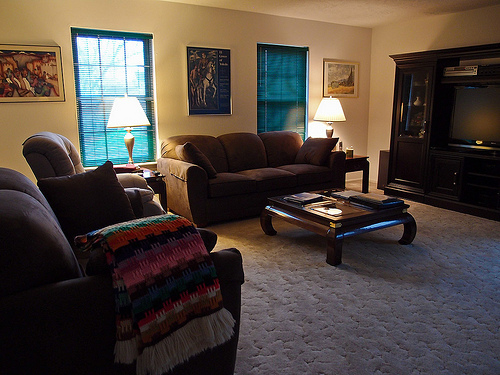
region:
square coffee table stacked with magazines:
[258, 184, 419, 269]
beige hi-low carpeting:
[195, 187, 497, 374]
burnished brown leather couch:
[156, 128, 349, 228]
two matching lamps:
[105, 92, 347, 164]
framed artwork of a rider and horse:
[183, 44, 235, 119]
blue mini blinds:
[67, 25, 160, 168]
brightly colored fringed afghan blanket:
[73, 210, 238, 374]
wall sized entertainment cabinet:
[382, 38, 499, 223]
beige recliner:
[21, 128, 168, 213]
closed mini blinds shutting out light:
[254, 39, 311, 143]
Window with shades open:
[69, 26, 158, 166]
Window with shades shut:
[255, 41, 308, 140]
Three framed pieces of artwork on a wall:
[3, 41, 361, 116]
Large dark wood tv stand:
[381, 38, 498, 223]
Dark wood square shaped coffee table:
[254, 187, 419, 269]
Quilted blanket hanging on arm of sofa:
[76, 213, 238, 370]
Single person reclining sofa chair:
[23, 131, 165, 221]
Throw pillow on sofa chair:
[33, 157, 138, 231]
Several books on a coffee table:
[282, 186, 402, 211]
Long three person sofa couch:
[157, 128, 350, 227]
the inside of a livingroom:
[11, 8, 478, 347]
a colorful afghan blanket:
[78, 212, 245, 373]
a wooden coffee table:
[259, 173, 421, 275]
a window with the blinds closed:
[258, 47, 310, 134]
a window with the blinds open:
[76, 36, 155, 162]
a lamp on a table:
[101, 88, 149, 173]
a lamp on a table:
[311, 93, 351, 147]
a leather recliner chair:
[15, 128, 165, 216]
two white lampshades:
[87, 101, 377, 143]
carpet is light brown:
[318, 257, 406, 367]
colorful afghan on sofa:
[62, 195, 262, 345]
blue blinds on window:
[74, 80, 151, 170]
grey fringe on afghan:
[127, 294, 237, 368]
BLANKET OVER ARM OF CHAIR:
[69, 211, 244, 370]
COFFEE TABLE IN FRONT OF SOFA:
[249, 181, 428, 270]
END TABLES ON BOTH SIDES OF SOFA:
[99, 143, 374, 197]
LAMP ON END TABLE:
[99, 89, 169, 177]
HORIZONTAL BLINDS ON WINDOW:
[62, 29, 163, 163]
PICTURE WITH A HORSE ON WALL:
[178, 34, 246, 128]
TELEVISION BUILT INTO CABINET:
[445, 73, 496, 160]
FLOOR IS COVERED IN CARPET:
[243, 195, 489, 366]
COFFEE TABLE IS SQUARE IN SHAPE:
[247, 182, 424, 243]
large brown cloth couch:
[159, 132, 343, 229]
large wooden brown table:
[260, 188, 418, 266]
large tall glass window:
[70, 26, 155, 166]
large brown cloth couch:
[0, 164, 247, 373]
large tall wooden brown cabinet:
[378, 42, 497, 224]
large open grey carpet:
[198, 179, 499, 373]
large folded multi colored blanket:
[75, 214, 238, 374]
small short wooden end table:
[342, 156, 371, 194]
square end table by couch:
[257, 183, 427, 272]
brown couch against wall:
[155, 115, 354, 224]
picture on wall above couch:
[179, 39, 240, 121]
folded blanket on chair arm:
[66, 209, 242, 374]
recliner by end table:
[22, 126, 172, 224]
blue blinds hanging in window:
[255, 39, 312, 144]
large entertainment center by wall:
[370, 44, 498, 223]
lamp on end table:
[100, 89, 152, 169]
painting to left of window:
[0, 41, 67, 101]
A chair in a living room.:
[18, 123, 159, 235]